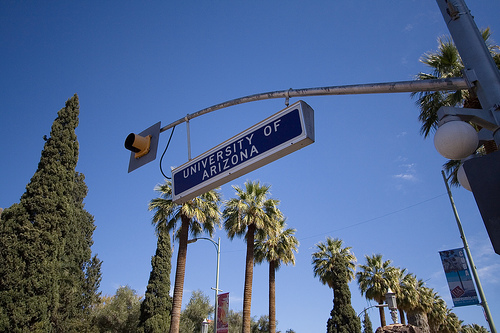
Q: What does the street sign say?
A: UNIVERSITY OF ARIZONA.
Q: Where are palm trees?
A: Along the street.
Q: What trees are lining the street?
A: Palm trees and evergreens.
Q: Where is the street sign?
A: Above the road.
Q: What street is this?
A: University of Arizona.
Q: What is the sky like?
A: Cloudless.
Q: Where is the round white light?
A: On the pole.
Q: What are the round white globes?
A: Street lights.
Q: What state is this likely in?
A: Arizona.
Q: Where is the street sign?
A: Hanging on silver bar.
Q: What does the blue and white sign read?
A: University of arizona.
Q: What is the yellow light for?
A: Traffic signal.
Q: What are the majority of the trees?
A: Palm.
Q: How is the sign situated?
A: Horizontally.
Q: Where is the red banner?
A: Streetlamp on left.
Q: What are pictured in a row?
A: Green and yellow palm trees.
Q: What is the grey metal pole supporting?
A: A traffic light and a street sign.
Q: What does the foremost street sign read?
A: University of Arizona.